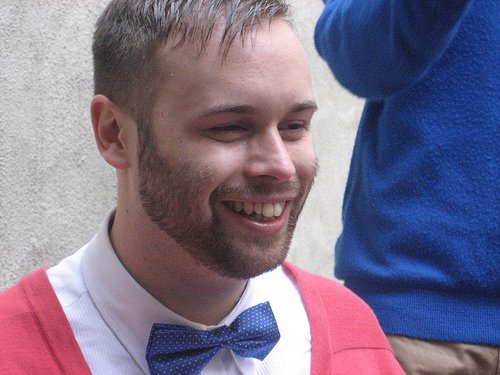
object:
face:
[132, 18, 319, 281]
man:
[0, 0, 406, 374]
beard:
[134, 119, 320, 280]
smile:
[217, 194, 297, 234]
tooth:
[232, 200, 242, 212]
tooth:
[242, 202, 252, 214]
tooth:
[252, 201, 262, 215]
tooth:
[272, 201, 283, 217]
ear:
[90, 93, 131, 170]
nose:
[242, 122, 295, 184]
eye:
[202, 123, 247, 136]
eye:
[278, 120, 309, 134]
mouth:
[218, 194, 295, 234]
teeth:
[261, 202, 274, 218]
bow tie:
[145, 300, 280, 375]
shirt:
[45, 202, 312, 374]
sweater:
[0, 259, 406, 375]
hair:
[91, 0, 298, 115]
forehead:
[159, 16, 314, 108]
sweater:
[313, 0, 499, 344]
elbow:
[313, 0, 471, 102]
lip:
[231, 201, 298, 232]